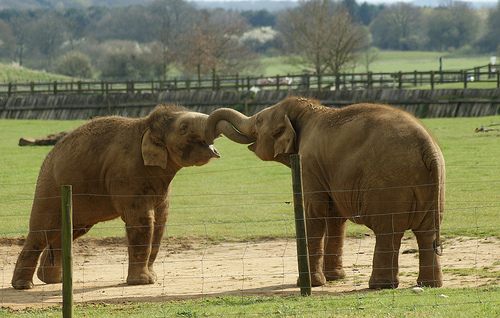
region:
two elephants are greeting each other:
[12, 90, 454, 295]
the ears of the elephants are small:
[137, 92, 299, 174]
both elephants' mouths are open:
[141, 90, 298, 178]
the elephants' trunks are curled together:
[192, 101, 269, 159]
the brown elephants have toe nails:
[12, 263, 444, 300]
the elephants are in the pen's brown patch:
[1, 193, 499, 317]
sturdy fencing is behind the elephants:
[3, 65, 498, 127]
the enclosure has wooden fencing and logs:
[8, 66, 498, 128]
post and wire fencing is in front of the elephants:
[6, 162, 498, 311]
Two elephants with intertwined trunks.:
[11, 92, 445, 288]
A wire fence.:
[0, 172, 498, 315]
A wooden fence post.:
[288, 152, 315, 299]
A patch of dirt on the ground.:
[0, 224, 499, 306]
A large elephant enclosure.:
[0, 78, 497, 316]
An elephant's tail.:
[430, 168, 445, 257]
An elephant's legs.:
[300, 212, 446, 287]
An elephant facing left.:
[208, 94, 447, 290]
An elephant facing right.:
[11, 102, 251, 288]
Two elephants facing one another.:
[8, 96, 451, 292]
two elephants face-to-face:
[14, 85, 460, 307]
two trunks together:
[150, 87, 295, 170]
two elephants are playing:
[16, 77, 456, 306]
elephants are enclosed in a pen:
[0, 49, 499, 316]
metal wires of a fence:
[0, 173, 499, 316]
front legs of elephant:
[291, 205, 351, 292]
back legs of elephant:
[364, 223, 454, 295]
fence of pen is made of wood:
[1, 58, 490, 120]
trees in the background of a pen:
[5, 6, 499, 120]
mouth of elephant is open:
[168, 103, 232, 167]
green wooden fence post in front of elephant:
[288, 152, 311, 297]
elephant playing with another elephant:
[12, 103, 253, 288]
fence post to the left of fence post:
[60, 185, 75, 316]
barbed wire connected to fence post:
[70, 189, 295, 197]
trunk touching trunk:
[204, 106, 249, 142]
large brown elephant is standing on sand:
[205, 97, 451, 290]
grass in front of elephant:
[13, 287, 498, 317]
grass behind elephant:
[1, 115, 499, 236]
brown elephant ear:
[142, 131, 168, 170]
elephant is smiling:
[12, 108, 256, 287]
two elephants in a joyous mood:
[4, 80, 450, 305]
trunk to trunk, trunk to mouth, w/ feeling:
[195, 95, 255, 162]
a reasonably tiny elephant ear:
[136, 125, 176, 171]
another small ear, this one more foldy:
[269, 113, 303, 162]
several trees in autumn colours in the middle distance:
[166, 1, 378, 98]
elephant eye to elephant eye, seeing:
[172, 112, 262, 142]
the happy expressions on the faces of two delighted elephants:
[174, 106, 266, 165]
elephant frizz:
[50, 93, 403, 148]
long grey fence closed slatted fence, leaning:
[0, 65, 498, 116]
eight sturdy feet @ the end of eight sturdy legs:
[5, 217, 456, 305]